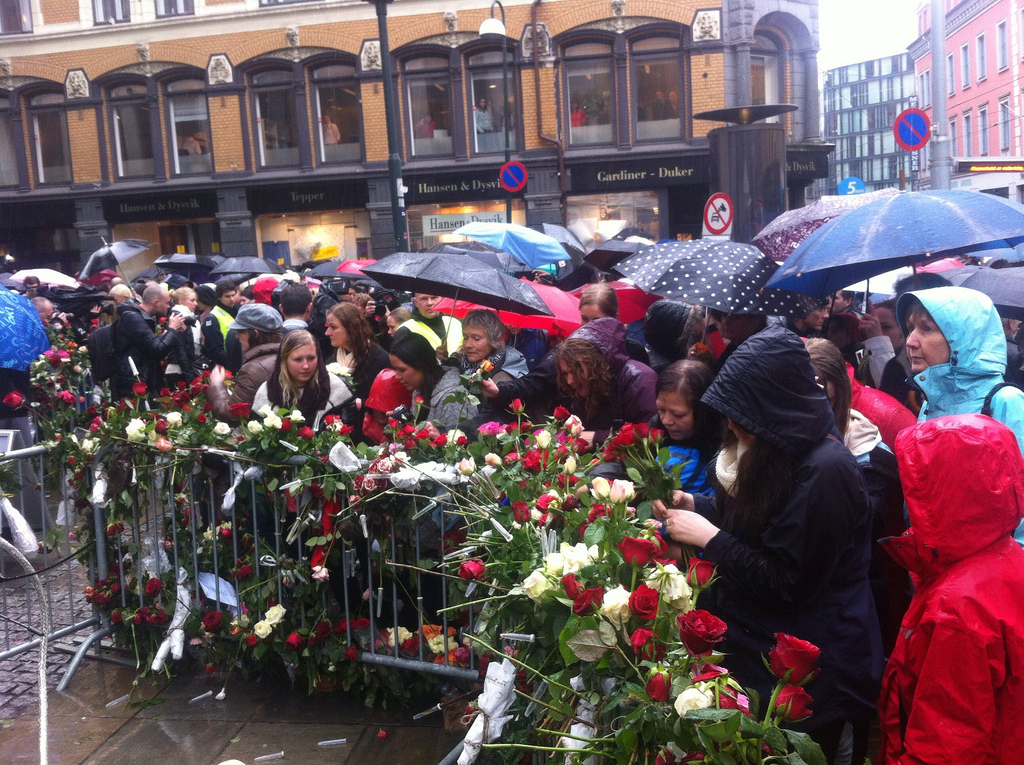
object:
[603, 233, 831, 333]
umbrella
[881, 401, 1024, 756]
person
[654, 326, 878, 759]
woman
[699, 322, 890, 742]
raincoat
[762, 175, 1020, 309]
umbrella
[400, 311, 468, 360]
vest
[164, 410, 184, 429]
rose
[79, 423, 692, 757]
railing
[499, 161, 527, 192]
sign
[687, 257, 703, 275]
dots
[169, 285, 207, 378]
woman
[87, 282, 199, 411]
man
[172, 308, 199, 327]
camera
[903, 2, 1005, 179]
wall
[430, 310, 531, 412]
person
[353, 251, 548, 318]
umbrella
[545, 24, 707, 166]
window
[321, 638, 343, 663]
leaf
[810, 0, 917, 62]
sky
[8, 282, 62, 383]
umbrella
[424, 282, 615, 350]
ubrella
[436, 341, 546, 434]
coat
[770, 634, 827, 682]
flower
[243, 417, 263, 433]
plant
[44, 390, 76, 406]
plant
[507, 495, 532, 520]
plant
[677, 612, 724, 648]
plant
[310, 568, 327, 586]
plant